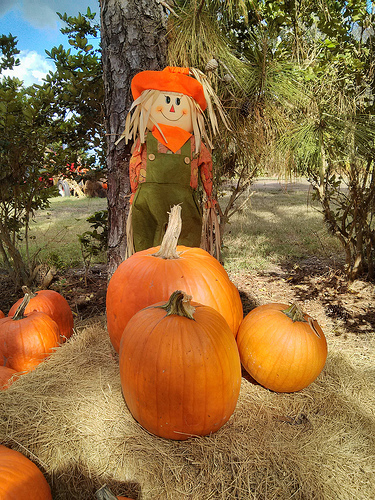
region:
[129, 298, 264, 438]
the watermellon is huge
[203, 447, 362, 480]
the grass is dry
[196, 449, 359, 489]
the grass is brown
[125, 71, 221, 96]
the aht is orange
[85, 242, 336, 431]
there are three pumpkins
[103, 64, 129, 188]
the bark is grey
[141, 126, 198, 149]
the scar is orange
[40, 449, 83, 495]
a shadow is on the grass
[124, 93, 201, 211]
the girl has a smile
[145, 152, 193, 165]
the buttons are brown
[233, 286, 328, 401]
an orange pumpkin in a patch.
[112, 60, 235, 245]
a scarecrow in pumpkin patch.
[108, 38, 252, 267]
a scarecrow standing near a tree.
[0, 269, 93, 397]
a couple of large pumpkins.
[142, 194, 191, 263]
a brown stem on a pumpkin.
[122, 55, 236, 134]
the face of a scarecrow.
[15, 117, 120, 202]
a house in a forest.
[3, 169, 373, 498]
a field of dry grass.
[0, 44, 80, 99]
a cloud in a blue sky.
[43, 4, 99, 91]
green leafy tree branches.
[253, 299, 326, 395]
small pumkin on hay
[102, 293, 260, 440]
medium pumpkin on hay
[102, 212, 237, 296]
large pumkin on hay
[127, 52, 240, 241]
scare crow waring orange hat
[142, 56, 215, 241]
scare crow next to a tree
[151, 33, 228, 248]
scare crow wearing green overalls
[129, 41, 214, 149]
scare crow wearing orange scarf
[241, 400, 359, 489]
brown hay with pumkins on top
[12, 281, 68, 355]
pumpkins on the side of hay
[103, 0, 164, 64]
tree trunk next to scarecrow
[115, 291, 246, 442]
a large orange pumpkin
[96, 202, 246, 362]
a large orange pumpkin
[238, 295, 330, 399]
a small orange pumpkin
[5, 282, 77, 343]
a small orange pumpkin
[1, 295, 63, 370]
a small orange pumpkin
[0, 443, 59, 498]
a small orange pumpkin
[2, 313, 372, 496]
a large bale of hay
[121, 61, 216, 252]
a decorative scarecrow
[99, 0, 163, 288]
a large barky tree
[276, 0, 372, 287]
a large bush in background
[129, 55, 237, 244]
A scarecrow leans against the tree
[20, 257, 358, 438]
A group of pumpkins sits on the hay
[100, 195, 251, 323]
The large pumpkin has a long stem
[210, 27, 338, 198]
Pine needles behind the pumpkins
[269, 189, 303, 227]
There is short grass behind the scarecrow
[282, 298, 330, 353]
This pumpkin has a short stem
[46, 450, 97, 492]
A shadow on the hay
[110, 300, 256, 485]
The pumpkin is sitting on the hay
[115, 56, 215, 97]
The scarecrow has an orange hat on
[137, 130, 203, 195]
The scarecrow has buttons on the front of it